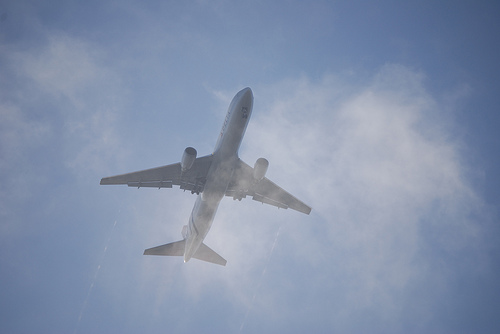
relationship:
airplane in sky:
[100, 85, 314, 273] [204, 48, 234, 70]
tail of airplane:
[141, 240, 228, 268] [100, 85, 314, 273]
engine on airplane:
[178, 140, 200, 194] [100, 85, 314, 273]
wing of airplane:
[109, 144, 212, 202] [100, 85, 314, 273]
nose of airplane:
[220, 84, 259, 118] [100, 85, 314, 273]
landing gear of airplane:
[188, 171, 204, 195] [100, 85, 314, 273]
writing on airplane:
[216, 100, 234, 147] [100, 85, 314, 273]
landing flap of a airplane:
[128, 181, 174, 189] [100, 85, 314, 273]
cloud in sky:
[363, 91, 389, 139] [204, 48, 234, 70]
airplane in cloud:
[100, 85, 314, 273] [363, 91, 389, 139]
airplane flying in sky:
[100, 85, 314, 273] [204, 48, 234, 70]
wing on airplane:
[109, 144, 212, 202] [100, 85, 314, 273]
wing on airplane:
[236, 162, 324, 220] [100, 85, 314, 273]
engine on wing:
[178, 140, 200, 194] [109, 144, 212, 202]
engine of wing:
[250, 160, 271, 206] [236, 162, 324, 220]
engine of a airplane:
[178, 140, 200, 194] [100, 85, 314, 273]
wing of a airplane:
[109, 144, 212, 202] [100, 85, 314, 273]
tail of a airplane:
[141, 240, 228, 268] [100, 85, 314, 273]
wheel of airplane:
[241, 110, 251, 122] [100, 85, 314, 273]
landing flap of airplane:
[120, 180, 177, 191] [100, 85, 314, 273]